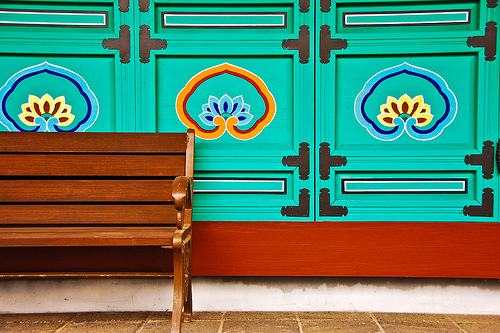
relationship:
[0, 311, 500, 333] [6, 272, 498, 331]
tile on floor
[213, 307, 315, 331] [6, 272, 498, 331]
tile on floor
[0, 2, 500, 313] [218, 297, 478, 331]
wall above tile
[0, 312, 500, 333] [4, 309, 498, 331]
grout on tile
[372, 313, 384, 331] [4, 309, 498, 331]
grout on tile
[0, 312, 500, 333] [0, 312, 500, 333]
grout on grout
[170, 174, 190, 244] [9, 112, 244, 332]
arm on bench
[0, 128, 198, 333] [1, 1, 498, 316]
bench obscuring wall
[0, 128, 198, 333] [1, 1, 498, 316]
bench in front of wall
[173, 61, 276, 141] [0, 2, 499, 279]
design on wall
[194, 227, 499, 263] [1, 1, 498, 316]
base on wall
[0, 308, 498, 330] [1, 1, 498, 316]
pavement in front of wall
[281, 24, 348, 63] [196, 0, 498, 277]
inlay on wall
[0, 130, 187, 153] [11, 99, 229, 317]
slat on bench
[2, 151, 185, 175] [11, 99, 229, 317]
slat on bench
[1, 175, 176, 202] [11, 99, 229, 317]
slat on bench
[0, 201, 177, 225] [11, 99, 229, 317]
slat on bench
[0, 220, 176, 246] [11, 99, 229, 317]
slat on bench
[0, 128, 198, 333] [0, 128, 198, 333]
bench on bench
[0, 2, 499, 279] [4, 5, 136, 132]
wall looks like door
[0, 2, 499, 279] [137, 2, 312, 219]
wall looks like door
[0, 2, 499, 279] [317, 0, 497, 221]
wall looks like door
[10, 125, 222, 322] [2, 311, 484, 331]
bench on sidewalk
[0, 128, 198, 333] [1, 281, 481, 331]
bench on sidewalk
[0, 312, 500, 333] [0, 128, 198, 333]
sidewalk with bench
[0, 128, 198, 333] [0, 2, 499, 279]
bench against wall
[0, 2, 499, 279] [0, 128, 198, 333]
wall with bench